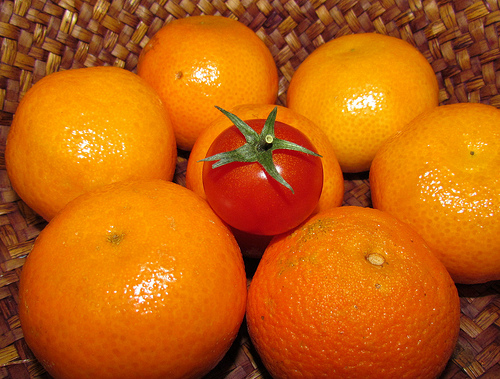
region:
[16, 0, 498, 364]
fruit and vegetables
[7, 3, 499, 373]
a wicker basket with fruit and vegetables in it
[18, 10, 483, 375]
oranges in a basket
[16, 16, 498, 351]
oranges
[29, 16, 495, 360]
seven oranges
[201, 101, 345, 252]
one tomatoe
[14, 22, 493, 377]
seven oranges with one tomatoe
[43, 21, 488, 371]
the tomatoe is on top of the oranges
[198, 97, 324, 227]
the tomatoe has a green stem with leaves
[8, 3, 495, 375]
the basket holds fruit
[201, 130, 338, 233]
tomato in a basket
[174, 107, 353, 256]
tomato on top of oranges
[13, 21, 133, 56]
basket with fruit in it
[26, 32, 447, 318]
7 oranges in a basket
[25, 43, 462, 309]
7 oranges in a circle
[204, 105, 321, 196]
green leaf on tomato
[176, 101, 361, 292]
tomato resting on 3 oranges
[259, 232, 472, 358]
orange with no glare from the light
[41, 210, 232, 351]
orange with bright glare from the light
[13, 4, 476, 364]
Oranges in basket.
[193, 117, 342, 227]
Tomato on top of the oranges.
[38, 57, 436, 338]
Fruit in the basket.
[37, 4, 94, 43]
The basket is wicker.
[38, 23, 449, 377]
7 oranges in the basket.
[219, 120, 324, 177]
The tomato's stem is green.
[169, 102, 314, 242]
The tomato is red.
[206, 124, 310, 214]
The tomato is on top of one orange.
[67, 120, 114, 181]
The orange has a bright spot on it.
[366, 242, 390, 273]
The center of the orange is tan in color.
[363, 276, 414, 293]
small brown spot on orange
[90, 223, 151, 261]
large spot in middle of an orange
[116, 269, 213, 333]
bright shine on the orange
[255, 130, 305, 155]
green stem in tomato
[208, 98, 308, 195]
green leaves on the stem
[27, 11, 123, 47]
brown wicker in the background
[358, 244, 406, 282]
small hole in top of orange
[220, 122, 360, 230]
small shiny round tomato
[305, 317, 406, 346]
small grooves in the orange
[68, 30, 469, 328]
bunch of oranges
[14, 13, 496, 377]
a group of oranges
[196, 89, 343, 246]
a red tomato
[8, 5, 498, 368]
the basket is brown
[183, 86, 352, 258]
the tomato has a green leaf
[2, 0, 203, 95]
the basket is weaved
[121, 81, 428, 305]
the tomato is on top of an orange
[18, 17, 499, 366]
the oranges are in a circle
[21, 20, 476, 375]
the oranges are shiny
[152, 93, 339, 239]
the tomato has a stem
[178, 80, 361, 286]
the tomato is shiny